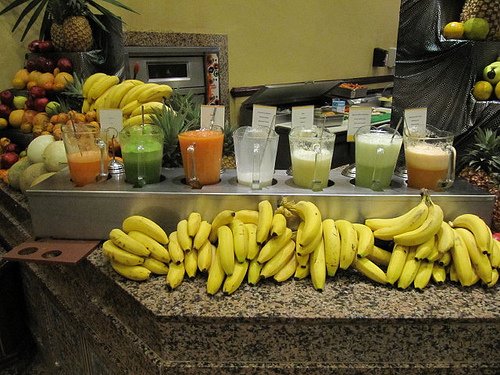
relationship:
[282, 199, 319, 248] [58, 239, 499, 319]
banana on counter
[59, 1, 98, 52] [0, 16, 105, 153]
pineapple on shelf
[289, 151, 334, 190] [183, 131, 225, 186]
smoothy and liquid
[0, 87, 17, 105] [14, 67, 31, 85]
apple and orange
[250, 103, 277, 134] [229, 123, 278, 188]
sign behind pitcher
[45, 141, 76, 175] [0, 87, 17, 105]
melon by apple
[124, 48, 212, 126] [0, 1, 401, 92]
oven on wall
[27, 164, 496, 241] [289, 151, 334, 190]
bin of smoothy